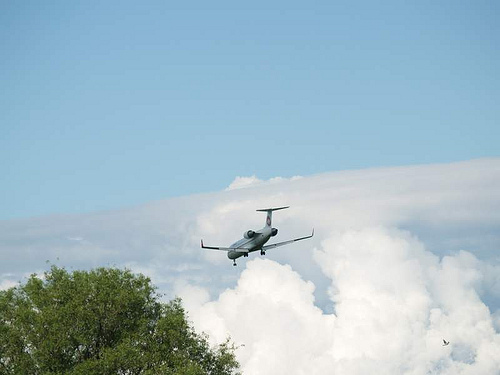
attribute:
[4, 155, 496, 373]
clouds — white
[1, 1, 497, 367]
sky — blue, clear, sunny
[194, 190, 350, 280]
plane — gray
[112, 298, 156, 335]
leaves — tree, green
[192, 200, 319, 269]
airplane — tail 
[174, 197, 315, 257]
airplane — wing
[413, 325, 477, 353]
bird — flying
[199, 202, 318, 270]
plane — gray, large, commercial, silver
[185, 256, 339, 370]
cloud — white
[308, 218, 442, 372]
cloud — white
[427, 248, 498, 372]
cloud — white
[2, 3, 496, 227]
sky — blue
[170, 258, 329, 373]
cloud — white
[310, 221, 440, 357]
cloud — white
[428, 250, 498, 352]
cloud — white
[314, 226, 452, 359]
cloud — white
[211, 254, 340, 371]
cloud — white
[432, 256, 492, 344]
cloud — white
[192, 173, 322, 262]
cloud — white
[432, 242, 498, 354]
cloud — white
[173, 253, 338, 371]
cloud — white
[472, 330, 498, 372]
cloud — white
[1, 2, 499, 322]
sky — blue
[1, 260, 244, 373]
tree — bushy, green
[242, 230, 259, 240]
engine — silver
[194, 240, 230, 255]
wing — long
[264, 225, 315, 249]
wing — long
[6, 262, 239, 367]
top — tree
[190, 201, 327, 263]
aircraft — low flying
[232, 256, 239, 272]
gear — landing, extended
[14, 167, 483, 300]
bank — cloud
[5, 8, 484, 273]
sky — lower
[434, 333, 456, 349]
bird — flying on the lower right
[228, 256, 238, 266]
gear — landing